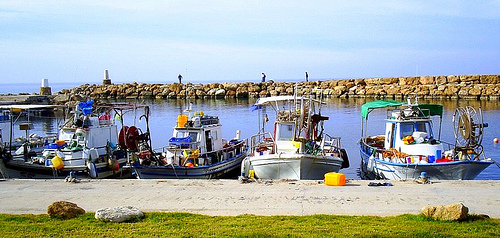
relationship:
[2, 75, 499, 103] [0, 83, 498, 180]
rock wall in water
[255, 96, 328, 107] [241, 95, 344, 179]
roof on boat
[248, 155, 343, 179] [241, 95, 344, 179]
bow of boat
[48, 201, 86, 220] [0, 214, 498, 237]
rock on grass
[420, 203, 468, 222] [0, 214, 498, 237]
rock on grass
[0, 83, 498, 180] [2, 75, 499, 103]
water around rock wall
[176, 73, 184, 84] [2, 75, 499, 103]
person on rock wall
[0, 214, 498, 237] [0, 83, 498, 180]
grass near water